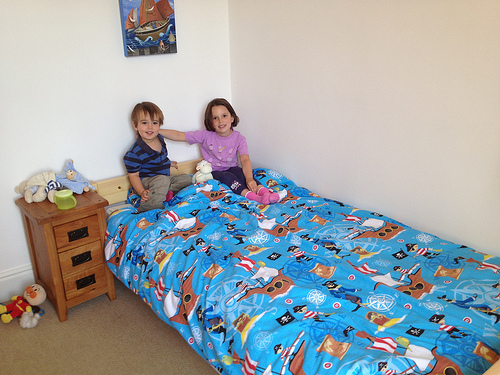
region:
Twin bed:
[91, 158, 498, 373]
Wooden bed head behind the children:
[87, 158, 206, 207]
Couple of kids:
[121, 98, 278, 210]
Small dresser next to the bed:
[16, 189, 118, 322]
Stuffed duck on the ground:
[0, 284, 47, 329]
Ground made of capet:
[0, 280, 215, 374]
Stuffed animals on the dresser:
[12, 153, 97, 202]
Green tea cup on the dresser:
[51, 188, 78, 215]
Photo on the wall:
[119, 0, 177, 59]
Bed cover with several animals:
[96, 167, 499, 374]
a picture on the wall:
[120, 0, 177, 55]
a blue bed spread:
[141, 184, 467, 373]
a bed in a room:
[82, 118, 498, 368]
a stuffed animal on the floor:
[4, 279, 46, 331]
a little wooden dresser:
[36, 193, 121, 309]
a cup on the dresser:
[53, 189, 78, 209]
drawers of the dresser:
[65, 220, 104, 292]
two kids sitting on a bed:
[109, 93, 431, 362]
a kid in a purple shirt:
[196, 92, 281, 204]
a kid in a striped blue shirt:
[127, 108, 192, 210]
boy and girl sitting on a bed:
[120, 93, 300, 215]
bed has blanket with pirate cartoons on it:
[100, 166, 499, 373]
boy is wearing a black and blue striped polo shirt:
[120, 98, 193, 210]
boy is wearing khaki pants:
[122, 102, 194, 212]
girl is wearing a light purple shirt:
[166, 99, 289, 209]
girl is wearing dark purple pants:
[166, 88, 291, 208]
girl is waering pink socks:
[166, 97, 291, 206]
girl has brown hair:
[164, 94, 294, 206]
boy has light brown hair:
[117, 97, 205, 209]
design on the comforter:
[235, 264, 297, 305]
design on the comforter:
[292, 296, 328, 327]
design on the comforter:
[229, 319, 259, 348]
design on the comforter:
[205, 261, 229, 288]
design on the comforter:
[163, 273, 195, 320]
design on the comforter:
[148, 253, 188, 280]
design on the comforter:
[124, 250, 146, 268]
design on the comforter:
[378, 267, 439, 304]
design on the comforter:
[424, 313, 466, 346]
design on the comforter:
[418, 313, 463, 341]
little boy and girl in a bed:
[115, 86, 281, 227]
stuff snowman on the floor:
[1, 280, 55, 332]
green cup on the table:
[49, 182, 85, 214]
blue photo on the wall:
[111, 0, 190, 68]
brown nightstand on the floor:
[20, 199, 118, 306]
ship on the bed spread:
[222, 247, 289, 303]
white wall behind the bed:
[323, 44, 481, 195]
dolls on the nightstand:
[60, 159, 105, 194]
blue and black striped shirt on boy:
[125, 143, 177, 173]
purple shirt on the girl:
[187, 128, 253, 170]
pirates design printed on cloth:
[306, 278, 391, 343]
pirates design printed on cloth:
[223, 277, 305, 345]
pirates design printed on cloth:
[152, 256, 212, 332]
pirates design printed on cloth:
[176, 312, 273, 361]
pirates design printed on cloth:
[250, 308, 308, 365]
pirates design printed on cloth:
[418, 301, 459, 356]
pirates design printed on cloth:
[386, 246, 468, 328]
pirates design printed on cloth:
[278, 198, 340, 265]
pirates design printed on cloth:
[210, 183, 277, 255]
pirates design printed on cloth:
[157, 195, 214, 278]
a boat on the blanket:
[255, 264, 292, 293]